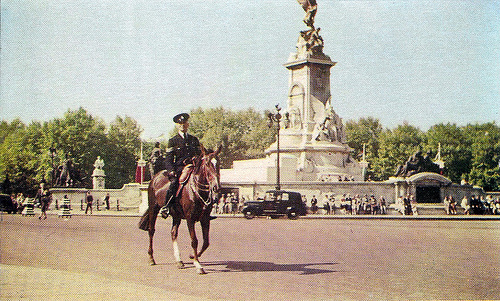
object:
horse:
[136, 142, 225, 276]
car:
[242, 189, 307, 220]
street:
[0, 214, 497, 298]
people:
[309, 195, 319, 215]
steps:
[308, 208, 498, 216]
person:
[31, 182, 52, 221]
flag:
[131, 157, 145, 183]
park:
[2, 117, 499, 217]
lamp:
[265, 101, 292, 201]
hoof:
[194, 262, 208, 276]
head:
[197, 142, 225, 202]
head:
[172, 112, 192, 133]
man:
[161, 112, 219, 222]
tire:
[243, 208, 256, 220]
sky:
[0, 0, 499, 145]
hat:
[172, 112, 190, 123]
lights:
[266, 112, 274, 129]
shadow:
[153, 260, 341, 276]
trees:
[24, 105, 120, 193]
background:
[0, 0, 500, 141]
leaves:
[10, 137, 20, 145]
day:
[3, 0, 500, 299]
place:
[4, 212, 499, 300]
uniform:
[162, 131, 204, 207]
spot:
[211, 157, 218, 168]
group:
[299, 193, 389, 216]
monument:
[265, 0, 354, 152]